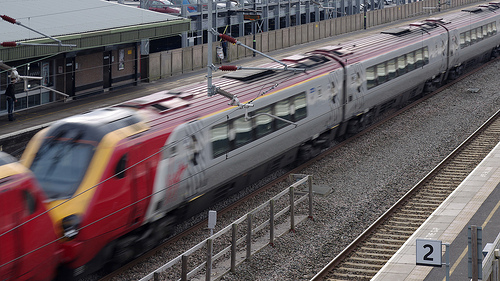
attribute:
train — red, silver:
[2, 1, 498, 280]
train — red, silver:
[44, 62, 379, 262]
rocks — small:
[288, 80, 464, 260]